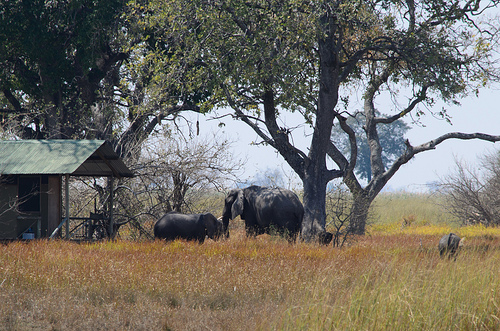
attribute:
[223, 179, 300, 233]
elephant — grey, mother, large, standing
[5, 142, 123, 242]
house — old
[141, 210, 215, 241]
elephant — small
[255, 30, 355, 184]
tree — tall, large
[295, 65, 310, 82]
leaves — green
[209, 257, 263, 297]
grass — tall, thin, brown, green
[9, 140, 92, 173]
roof — green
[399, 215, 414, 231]
elephant — grazing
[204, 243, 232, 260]
flowers — yellow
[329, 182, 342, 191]
tree — brown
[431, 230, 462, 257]
elephant — baby, small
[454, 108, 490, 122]
sky — blue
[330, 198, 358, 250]
bush — leafless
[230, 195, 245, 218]
ear — grey